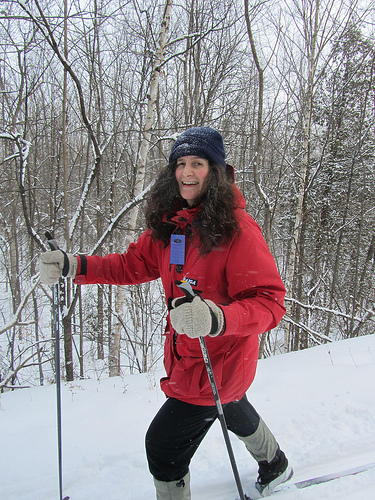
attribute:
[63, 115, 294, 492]
woman — skiing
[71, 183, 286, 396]
coat — red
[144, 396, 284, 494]
pants — black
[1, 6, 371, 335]
trees — snow-covered, bare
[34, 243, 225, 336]
gloves — gray, beige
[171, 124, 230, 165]
cap — knit, dark blue, black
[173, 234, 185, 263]
tag — blue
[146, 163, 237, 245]
hair — dark, long, curly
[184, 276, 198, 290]
label — black, white